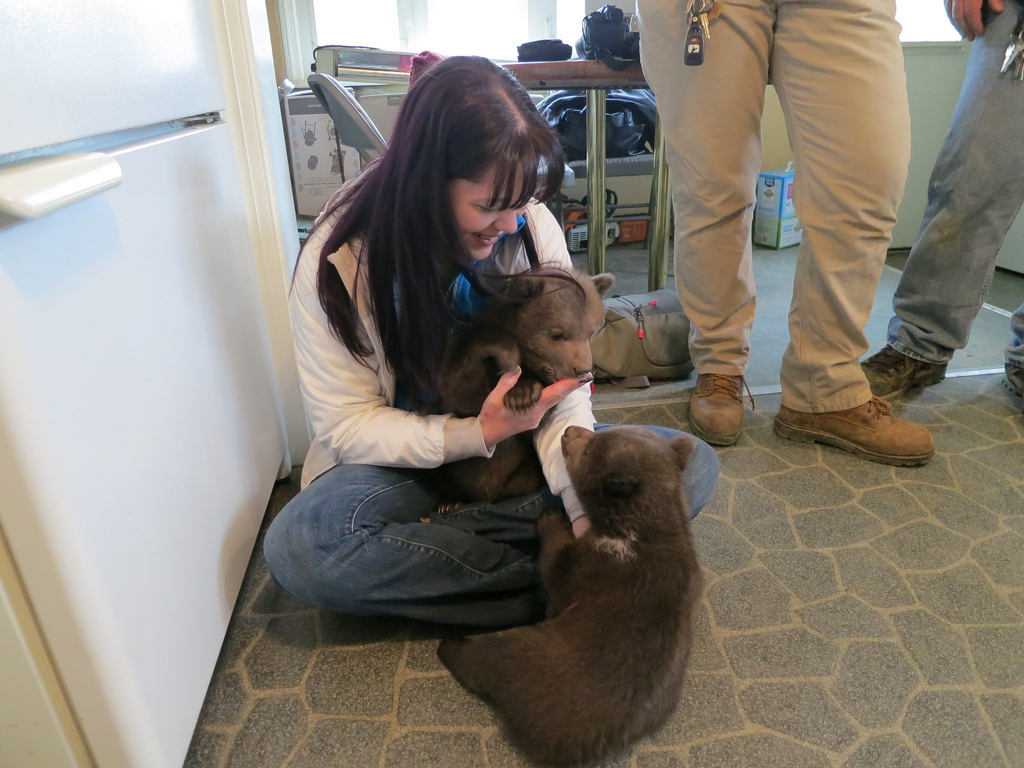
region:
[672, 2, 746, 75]
keys hanging from the pocket of the beige pants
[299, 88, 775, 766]
girl is playing with two baby bears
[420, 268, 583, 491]
girl is holding a baby brown bear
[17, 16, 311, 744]
white refrigerator by the girl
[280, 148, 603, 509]
girl is wearing a white jacket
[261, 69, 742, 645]
girl is sitting on the floor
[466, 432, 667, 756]
bear is laying on the floor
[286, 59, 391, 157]
metal folding chair behind the girl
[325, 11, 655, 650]
woman sitting on tile floor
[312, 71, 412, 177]
gray chair in background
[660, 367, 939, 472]
brown shoes on person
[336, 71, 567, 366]
dark straight hair on woman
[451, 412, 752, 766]
small brown bear by woman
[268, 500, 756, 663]
blue denim jeans on woman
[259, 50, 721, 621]
a woman holding a bear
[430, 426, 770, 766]
a bear on the floor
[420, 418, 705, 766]
the bear is brown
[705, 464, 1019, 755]
stone tiles on the floor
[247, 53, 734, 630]
a woman wearing jeans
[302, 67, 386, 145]
a metal folding chair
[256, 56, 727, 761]
a woman petting a bear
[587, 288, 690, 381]
a tan carrying bag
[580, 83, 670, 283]
metal legs on a table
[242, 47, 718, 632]
a woman with black hair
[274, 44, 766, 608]
a woman holding a bear cub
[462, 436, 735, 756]
a bear cub on the floor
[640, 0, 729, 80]
keys and car opener hanging from a pocket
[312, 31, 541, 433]
long brown hair on the woman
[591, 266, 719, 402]
a small gray duffle bag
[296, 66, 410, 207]
a gray metal chair behind the woman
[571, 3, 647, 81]
a black bag with strap on the table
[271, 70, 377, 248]
a white and gray box in the corner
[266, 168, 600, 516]
a white jacket on the woman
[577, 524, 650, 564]
a white spot on the bear cub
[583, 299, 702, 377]
a brown bag on the ground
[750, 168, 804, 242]
a box on the ground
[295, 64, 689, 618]
a lady in a white sweater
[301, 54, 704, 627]
a lady holding a bear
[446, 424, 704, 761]
a brown bear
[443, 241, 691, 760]
two baby bears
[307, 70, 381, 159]
the back of a chair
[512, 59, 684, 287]
a small table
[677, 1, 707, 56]
a set of car keys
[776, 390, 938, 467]
a brown boot